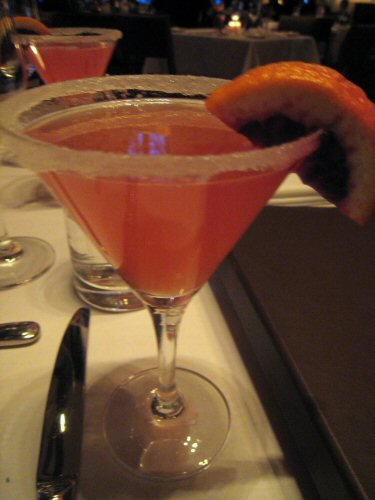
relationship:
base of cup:
[102, 365, 234, 480] [2, 68, 333, 482]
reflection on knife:
[53, 405, 70, 434] [42, 304, 82, 498]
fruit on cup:
[206, 62, 375, 227] [2, 68, 333, 482]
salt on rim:
[0, 134, 323, 185] [2, 71, 327, 190]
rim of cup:
[2, 71, 327, 190] [2, 68, 333, 482]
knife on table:
[33, 302, 90, 498] [2, 132, 362, 498]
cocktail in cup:
[29, 99, 294, 297] [2, 68, 333, 482]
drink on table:
[10, 25, 125, 140] [2, 132, 362, 498]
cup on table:
[2, 68, 333, 482] [2, 132, 362, 498]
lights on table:
[222, 12, 243, 35] [159, 23, 323, 91]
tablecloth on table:
[170, 25, 324, 81] [144, 27, 328, 87]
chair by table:
[108, 13, 178, 79] [137, 25, 321, 78]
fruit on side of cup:
[201, 59, 362, 228] [2, 68, 333, 482]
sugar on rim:
[39, 146, 174, 178] [2, 71, 327, 190]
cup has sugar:
[2, 68, 333, 482] [39, 146, 174, 178]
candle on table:
[222, 9, 245, 32] [144, 24, 321, 82]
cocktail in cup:
[29, 99, 294, 297] [2, 68, 332, 488]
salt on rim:
[40, 146, 243, 184] [2, 71, 344, 199]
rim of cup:
[2, 71, 344, 199] [2, 68, 333, 482]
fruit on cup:
[201, 59, 362, 228] [2, 68, 333, 482]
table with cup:
[2, 132, 362, 498] [2, 68, 333, 482]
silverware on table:
[34, 297, 117, 496] [2, 132, 362, 498]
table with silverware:
[2, 132, 362, 498] [24, 302, 113, 499]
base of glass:
[102, 365, 233, 480] [4, 67, 347, 482]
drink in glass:
[12, 25, 122, 88] [18, 20, 126, 87]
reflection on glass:
[182, 430, 216, 460] [4, 67, 347, 482]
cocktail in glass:
[29, 99, 294, 297] [4, 67, 347, 482]